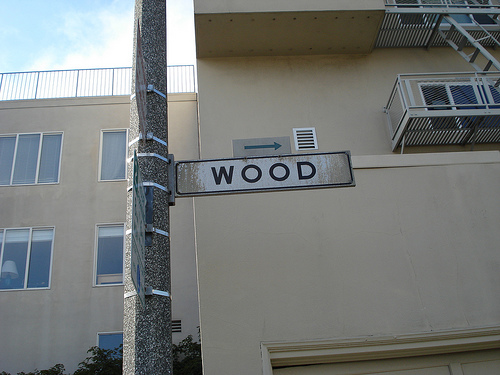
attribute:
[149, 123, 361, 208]
sign — black and white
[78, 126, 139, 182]
window — clear glass  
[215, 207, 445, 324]
building —  tan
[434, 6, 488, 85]
ladder — metal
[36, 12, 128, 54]
clouds — large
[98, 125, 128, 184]
window — clear glass 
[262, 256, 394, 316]
wall — white house 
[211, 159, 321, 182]
word — black 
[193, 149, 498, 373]
wall — white house 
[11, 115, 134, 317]
wall — white house 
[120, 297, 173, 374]
mast — concrete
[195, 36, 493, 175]
wall — white house 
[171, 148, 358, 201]
sign — street 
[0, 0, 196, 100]
cloud — white.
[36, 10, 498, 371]
building —  smooth.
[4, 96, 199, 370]
house — white house 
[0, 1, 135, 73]
sky —  blue.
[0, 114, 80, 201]
glass window — clear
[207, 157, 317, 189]
word — wood 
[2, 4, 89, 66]
sky — blue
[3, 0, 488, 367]
building — beige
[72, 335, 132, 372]
tree — green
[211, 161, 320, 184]
letters — black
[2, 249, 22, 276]
shade — white., lamp